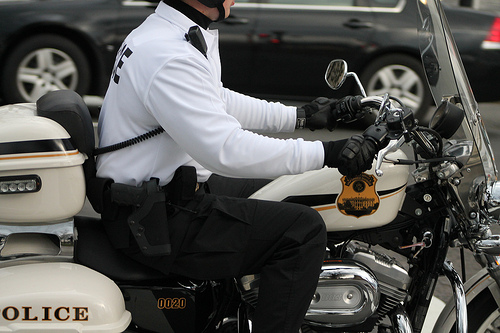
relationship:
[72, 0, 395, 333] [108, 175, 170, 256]
man sued gun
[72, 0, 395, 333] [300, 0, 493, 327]
man riding bike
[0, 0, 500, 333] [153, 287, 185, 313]
motorcycle sued number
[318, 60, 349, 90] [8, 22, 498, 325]
mirror of motorcycle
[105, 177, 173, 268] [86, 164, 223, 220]
gun on belt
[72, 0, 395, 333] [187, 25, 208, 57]
man in radio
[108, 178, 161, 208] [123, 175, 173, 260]
gun in holster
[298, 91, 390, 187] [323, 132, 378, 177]
hands are wearing glove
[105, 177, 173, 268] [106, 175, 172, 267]
gun in gun holster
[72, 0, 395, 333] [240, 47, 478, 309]
man on a bike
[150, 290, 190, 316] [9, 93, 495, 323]
number on bike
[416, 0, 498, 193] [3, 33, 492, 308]
front windshield on bike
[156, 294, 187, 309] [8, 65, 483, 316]
number 20 on motorcycle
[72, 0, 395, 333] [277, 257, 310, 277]
man wearing black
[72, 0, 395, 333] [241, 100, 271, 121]
man wearing white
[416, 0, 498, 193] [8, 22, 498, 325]
front windshield on motorcycle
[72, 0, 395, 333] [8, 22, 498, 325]
man on motorcycle